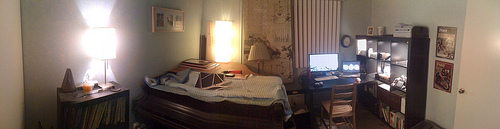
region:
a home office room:
[1, 1, 498, 126]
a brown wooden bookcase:
[55, 80, 130, 126]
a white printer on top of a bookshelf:
[391, 20, 430, 37]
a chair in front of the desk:
[320, 80, 358, 127]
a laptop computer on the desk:
[339, 59, 362, 79]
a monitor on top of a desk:
[307, 52, 340, 73]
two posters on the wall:
[430, 25, 458, 92]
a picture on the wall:
[150, 3, 185, 33]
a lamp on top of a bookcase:
[86, 28, 118, 90]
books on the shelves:
[376, 84, 406, 126]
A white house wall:
[468, 51, 498, 120]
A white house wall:
[425, 88, 459, 124]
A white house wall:
[463, 0, 498, 49]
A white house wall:
[415, 3, 473, 33]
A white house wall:
[327, 0, 389, 24]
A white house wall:
[137, 32, 187, 56]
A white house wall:
[19, 28, 58, 75]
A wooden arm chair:
[317, 83, 361, 122]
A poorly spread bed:
[150, 50, 268, 120]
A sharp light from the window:
[72, 1, 132, 86]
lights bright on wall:
[80, 2, 120, 80]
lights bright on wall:
[212, 16, 234, 58]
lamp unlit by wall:
[245, 42, 274, 72]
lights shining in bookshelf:
[357, 40, 416, 95]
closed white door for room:
[454, 14, 496, 127]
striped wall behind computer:
[292, 7, 343, 68]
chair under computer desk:
[315, 82, 366, 124]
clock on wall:
[343, 36, 350, 46]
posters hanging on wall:
[431, 22, 457, 89]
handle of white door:
[455, 87, 466, 93]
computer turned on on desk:
[309, 53, 339, 80]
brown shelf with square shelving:
[353, 35, 426, 125]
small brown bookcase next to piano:
[55, 80, 130, 125]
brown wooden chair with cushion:
[315, 81, 350, 122]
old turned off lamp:
[245, 41, 270, 71]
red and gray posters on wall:
[430, 20, 455, 91]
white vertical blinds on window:
[290, 0, 337, 62]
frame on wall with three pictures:
[149, 5, 184, 34]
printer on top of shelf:
[394, 23, 428, 36]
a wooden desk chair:
[320, 75, 358, 125]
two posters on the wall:
[432, 20, 461, 110]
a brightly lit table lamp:
[81, 13, 130, 96]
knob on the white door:
[456, 81, 467, 101]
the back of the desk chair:
[333, 84, 357, 115]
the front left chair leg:
[320, 102, 327, 127]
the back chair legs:
[325, 110, 365, 126]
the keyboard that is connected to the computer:
[311, 73, 344, 83]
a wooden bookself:
[54, 84, 141, 127]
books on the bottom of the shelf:
[381, 100, 401, 127]